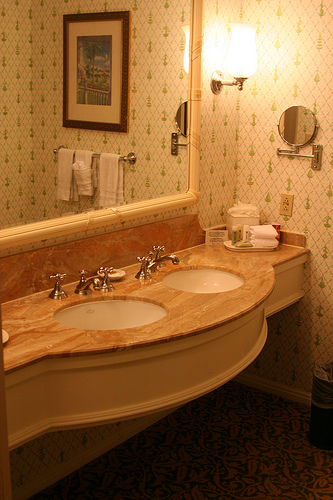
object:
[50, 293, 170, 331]
sink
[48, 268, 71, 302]
handle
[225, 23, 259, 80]
light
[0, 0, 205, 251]
mirror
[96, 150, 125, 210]
towel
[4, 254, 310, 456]
base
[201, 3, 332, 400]
wall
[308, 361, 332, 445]
trash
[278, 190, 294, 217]
outlet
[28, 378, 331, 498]
floor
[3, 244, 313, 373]
counter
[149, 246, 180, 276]
faucet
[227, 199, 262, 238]
tissue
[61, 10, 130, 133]
picture